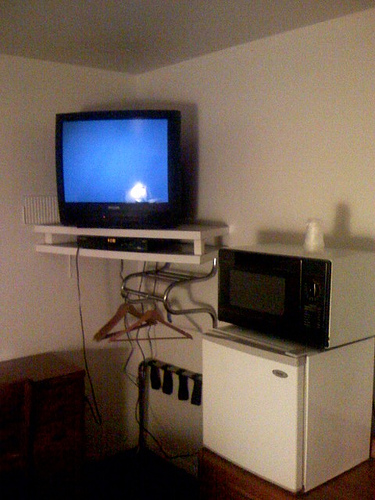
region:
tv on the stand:
[53, 109, 182, 230]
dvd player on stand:
[62, 228, 171, 250]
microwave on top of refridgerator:
[222, 232, 344, 348]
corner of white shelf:
[187, 227, 209, 261]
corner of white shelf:
[27, 219, 54, 250]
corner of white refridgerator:
[286, 479, 316, 496]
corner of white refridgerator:
[282, 353, 313, 384]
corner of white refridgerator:
[197, 329, 219, 353]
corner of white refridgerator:
[195, 437, 214, 458]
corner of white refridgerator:
[356, 450, 370, 465]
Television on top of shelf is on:
[53, 111, 184, 226]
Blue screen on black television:
[62, 118, 167, 202]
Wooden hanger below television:
[102, 301, 193, 342]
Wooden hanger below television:
[91, 289, 157, 342]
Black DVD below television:
[76, 234, 183, 252]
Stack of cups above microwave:
[303, 215, 324, 253]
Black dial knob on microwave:
[306, 281, 320, 299]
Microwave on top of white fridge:
[216, 240, 374, 348]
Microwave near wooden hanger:
[216, 238, 371, 346]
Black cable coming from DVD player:
[75, 241, 101, 426]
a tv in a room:
[31, 114, 246, 251]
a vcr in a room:
[72, 219, 190, 258]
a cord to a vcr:
[71, 253, 106, 418]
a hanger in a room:
[77, 258, 197, 352]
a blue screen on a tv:
[46, 106, 204, 230]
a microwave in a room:
[186, 235, 346, 342]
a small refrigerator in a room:
[179, 315, 344, 481]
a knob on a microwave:
[281, 250, 358, 333]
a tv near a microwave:
[31, 123, 370, 281]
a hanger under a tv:
[67, 127, 212, 375]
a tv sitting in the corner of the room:
[54, 105, 182, 225]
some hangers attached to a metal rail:
[95, 290, 178, 344]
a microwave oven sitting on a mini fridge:
[215, 241, 374, 349]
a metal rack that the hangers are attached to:
[118, 266, 219, 335]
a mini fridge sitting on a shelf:
[195, 322, 371, 493]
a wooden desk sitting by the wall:
[0, 352, 85, 489]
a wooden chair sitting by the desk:
[6, 378, 33, 486]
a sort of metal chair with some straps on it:
[134, 355, 210, 486]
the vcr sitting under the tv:
[74, 235, 153, 252]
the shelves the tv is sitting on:
[36, 217, 220, 271]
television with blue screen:
[43, 101, 195, 227]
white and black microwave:
[195, 235, 373, 357]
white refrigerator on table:
[176, 319, 373, 496]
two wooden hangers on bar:
[78, 287, 200, 357]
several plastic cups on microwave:
[292, 210, 333, 261]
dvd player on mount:
[62, 225, 187, 256]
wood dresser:
[0, 332, 103, 494]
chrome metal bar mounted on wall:
[112, 251, 221, 331]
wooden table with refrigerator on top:
[173, 439, 373, 497]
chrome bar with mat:
[115, 348, 202, 469]